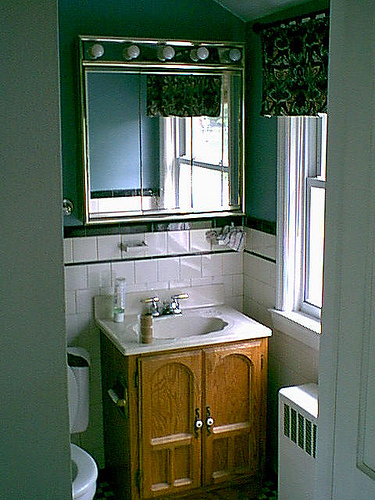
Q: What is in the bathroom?
A: The sink.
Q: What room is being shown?
A: Bathroom.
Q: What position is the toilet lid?
A: Raised.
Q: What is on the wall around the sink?
A: Tile.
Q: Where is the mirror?
A: Over the sink.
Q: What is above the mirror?
A: Lights.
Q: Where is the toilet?
A: Left side of the sink.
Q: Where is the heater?
A: Under the window.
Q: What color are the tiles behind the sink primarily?
A: White.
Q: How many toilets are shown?
A: One.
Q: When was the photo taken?
A: Daytime.